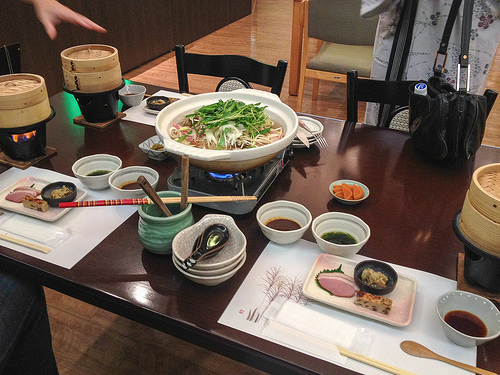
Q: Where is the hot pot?
A: In the middle of the table.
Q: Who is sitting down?
A: No one.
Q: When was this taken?
A: Meal time.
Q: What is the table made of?
A: Wood.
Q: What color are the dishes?
A: White.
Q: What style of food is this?
A: Asian.